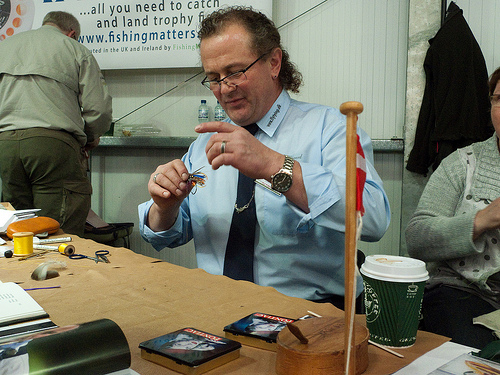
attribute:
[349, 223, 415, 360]
cup — coffee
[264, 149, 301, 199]
wrist — person's 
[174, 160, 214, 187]
bait — fishing 